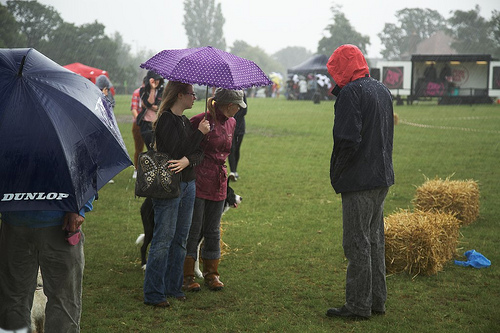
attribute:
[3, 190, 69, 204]
logo — dunlop, white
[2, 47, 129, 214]
umbrella — navy blue, blue, wet, dunlop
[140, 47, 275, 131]
umbrella — purple, polka dot, large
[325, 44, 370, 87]
hood — red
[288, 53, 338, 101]
tent — wet, festival tent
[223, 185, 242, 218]
dog — large, black, white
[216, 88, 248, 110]
cap — tan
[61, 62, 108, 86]
tent — obscured, red, bright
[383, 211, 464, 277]
hay — for animals, brown, large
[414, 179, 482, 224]
bale — for animals, brown, large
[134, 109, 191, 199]
handbag — butterfly-shaped, black, large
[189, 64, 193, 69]
polka dot — white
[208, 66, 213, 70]
polka dot — white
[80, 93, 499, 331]
field — large, green, grass, dark green, grassy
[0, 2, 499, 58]
sky — gray, hazy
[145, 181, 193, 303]
jeans — dark, blue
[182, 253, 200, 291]
boot — brown, leather, mid-calf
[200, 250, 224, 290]
boot — brown, leather, mid-calf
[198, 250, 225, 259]
trim — fur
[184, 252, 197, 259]
trim — fur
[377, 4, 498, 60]
trees — green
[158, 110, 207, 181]
top — black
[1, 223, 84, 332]
jeans — green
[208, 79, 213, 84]
polka dot — white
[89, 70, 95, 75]
dot — white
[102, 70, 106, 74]
dot — white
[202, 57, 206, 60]
polka dot — white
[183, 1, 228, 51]
tree — large, green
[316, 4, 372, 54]
tree — large, green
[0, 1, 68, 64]
tree — large, green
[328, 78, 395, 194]
parka — navy